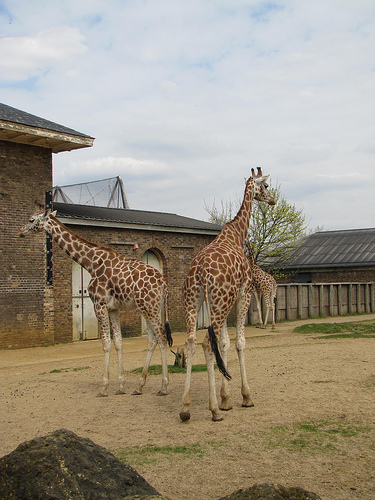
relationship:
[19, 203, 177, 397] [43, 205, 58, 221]
giraffe has ears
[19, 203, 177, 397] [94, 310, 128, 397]
giraffe has front legs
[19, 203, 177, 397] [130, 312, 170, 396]
giraffe has back legs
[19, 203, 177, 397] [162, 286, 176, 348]
giraffe has tail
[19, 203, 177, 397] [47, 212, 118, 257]
giraffe has mane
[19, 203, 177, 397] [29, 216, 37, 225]
giraffe has eye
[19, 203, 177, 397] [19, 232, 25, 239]
giraffe has mouth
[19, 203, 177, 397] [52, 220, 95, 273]
giraffe has neck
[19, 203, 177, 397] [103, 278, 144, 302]
giraffe has spots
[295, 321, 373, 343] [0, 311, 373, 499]
grass on ground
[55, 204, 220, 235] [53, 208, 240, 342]
roof on top of building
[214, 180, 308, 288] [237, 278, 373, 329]
tree near fence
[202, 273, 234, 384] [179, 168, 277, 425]
tail attached to giraffe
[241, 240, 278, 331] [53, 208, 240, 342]
giraffe next to building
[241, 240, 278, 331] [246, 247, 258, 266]
giraffe has neck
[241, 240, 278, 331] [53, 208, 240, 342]
giraffe standing beside building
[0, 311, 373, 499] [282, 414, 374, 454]
ground has grass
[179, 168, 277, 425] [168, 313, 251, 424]
giraffe has legs